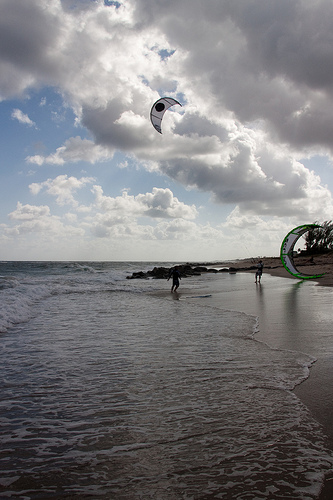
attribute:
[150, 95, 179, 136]
parasail — white, black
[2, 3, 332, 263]
sky — blue, cloudy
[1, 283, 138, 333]
wave — small, white, rolling, moving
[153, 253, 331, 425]
beach — wet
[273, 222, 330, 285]
parasail — green, white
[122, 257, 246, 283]
rocks — piled, sharp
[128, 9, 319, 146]
cloud — gray, white, puffy, dark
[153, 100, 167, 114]
circle — black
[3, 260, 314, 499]
water — partly white, splashing, coming in